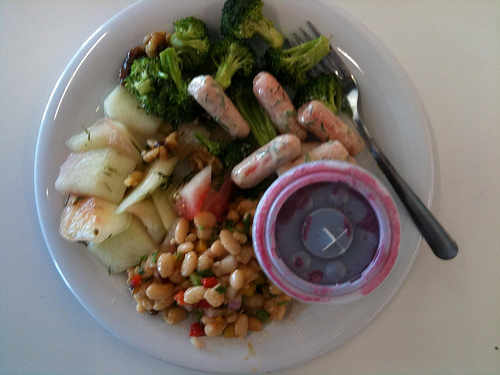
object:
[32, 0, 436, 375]
plate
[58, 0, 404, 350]
meal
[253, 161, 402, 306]
container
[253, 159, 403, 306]
sauce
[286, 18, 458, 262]
fork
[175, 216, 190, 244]
bean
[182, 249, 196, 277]
bean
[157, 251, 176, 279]
bean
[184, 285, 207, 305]
bean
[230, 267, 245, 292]
bean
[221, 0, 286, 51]
broccoli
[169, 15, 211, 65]
broccoli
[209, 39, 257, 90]
broccoli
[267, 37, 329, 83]
broccoli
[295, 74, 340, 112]
broccoli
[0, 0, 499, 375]
surface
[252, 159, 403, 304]
lid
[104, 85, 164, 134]
potato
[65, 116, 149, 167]
potato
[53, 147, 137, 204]
potato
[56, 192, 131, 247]
potato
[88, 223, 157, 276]
potato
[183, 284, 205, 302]
beans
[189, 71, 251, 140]
sausage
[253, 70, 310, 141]
sausage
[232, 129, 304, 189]
sausage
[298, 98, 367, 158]
sausage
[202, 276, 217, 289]
pepper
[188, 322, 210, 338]
tomato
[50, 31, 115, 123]
reflection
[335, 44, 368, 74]
reflection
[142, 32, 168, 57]
candy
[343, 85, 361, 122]
reflection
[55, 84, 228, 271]
salad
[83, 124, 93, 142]
dill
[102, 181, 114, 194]
dill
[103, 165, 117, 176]
dill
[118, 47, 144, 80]
walnut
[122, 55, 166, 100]
broccoli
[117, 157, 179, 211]
carrot